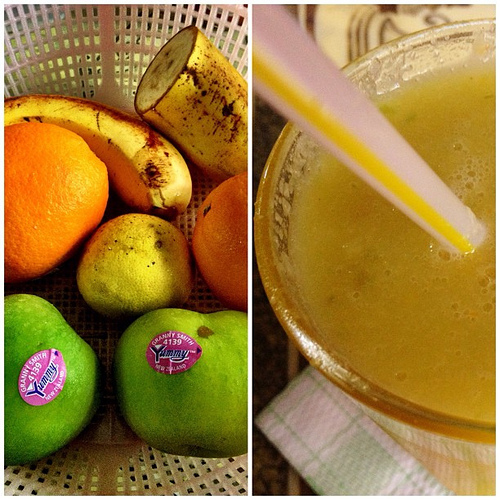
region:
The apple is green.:
[5, 287, 108, 481]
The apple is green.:
[108, 303, 252, 462]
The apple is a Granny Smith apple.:
[1, 286, 103, 474]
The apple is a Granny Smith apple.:
[109, 303, 256, 467]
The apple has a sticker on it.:
[3, 283, 105, 477]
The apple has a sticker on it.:
[112, 302, 249, 462]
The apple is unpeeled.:
[5, 290, 106, 478]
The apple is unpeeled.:
[111, 305, 251, 461]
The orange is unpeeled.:
[3, 115, 109, 289]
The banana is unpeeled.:
[2, 88, 197, 216]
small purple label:
[139, 327, 203, 372]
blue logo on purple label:
[142, 338, 202, 360]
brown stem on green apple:
[189, 320, 218, 340]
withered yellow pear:
[93, 206, 185, 298]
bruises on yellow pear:
[100, 237, 157, 283]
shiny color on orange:
[58, 181, 87, 206]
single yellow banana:
[105, 119, 177, 186]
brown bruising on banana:
[185, 73, 228, 118]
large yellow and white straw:
[291, 70, 404, 185]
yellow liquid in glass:
[335, 258, 421, 310]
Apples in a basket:
[2, 287, 264, 465]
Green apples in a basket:
[1, 284, 257, 465]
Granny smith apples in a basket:
[1, 290, 254, 462]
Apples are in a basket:
[2, 287, 258, 465]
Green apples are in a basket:
[0, 291, 251, 461]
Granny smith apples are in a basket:
[1, 289, 248, 469]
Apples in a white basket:
[1, 282, 254, 469]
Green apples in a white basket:
[0, 287, 250, 463]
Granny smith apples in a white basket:
[0, 290, 250, 465]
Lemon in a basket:
[55, 205, 201, 335]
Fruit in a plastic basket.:
[12, 30, 237, 455]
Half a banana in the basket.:
[126, 11, 243, 141]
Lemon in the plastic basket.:
[77, 195, 192, 317]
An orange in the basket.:
[7, 100, 110, 273]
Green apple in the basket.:
[116, 290, 235, 464]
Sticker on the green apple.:
[138, 320, 200, 382]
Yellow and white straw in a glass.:
[286, 41, 452, 216]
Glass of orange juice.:
[275, 250, 489, 375]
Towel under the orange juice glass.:
[254, 357, 384, 486]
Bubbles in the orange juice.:
[432, 118, 485, 212]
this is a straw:
[251, 70, 446, 238]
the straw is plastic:
[281, 85, 494, 335]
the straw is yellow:
[291, 123, 486, 261]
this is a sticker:
[96, 306, 223, 428]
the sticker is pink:
[133, 330, 178, 371]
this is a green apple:
[116, 369, 272, 441]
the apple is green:
[118, 305, 209, 486]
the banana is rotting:
[116, 119, 263, 130]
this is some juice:
[293, 139, 349, 497]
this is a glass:
[338, 376, 420, 436]